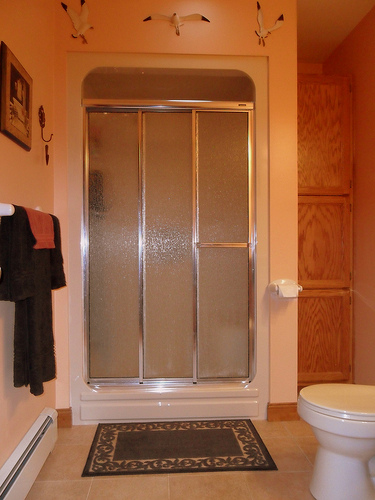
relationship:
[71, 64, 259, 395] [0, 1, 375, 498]
shower in corner of bathroom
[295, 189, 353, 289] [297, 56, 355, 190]
cabinet below cabinet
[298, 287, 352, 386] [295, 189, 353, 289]
wooden cabinet below cabinet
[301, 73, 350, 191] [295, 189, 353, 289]
cabinet above cabinet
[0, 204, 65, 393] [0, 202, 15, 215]
black towel hanging on rack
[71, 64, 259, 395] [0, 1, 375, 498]
shower in bathroom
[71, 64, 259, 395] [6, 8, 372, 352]
shower in bathroom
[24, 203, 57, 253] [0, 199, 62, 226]
towel on rack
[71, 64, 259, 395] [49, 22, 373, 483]
shower in corner of bathroom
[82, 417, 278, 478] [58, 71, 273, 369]
bath mat in front of shower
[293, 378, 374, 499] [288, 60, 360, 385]
toilet next to cabinet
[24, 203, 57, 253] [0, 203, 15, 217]
towel hanging on rack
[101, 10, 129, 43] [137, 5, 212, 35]
wall has decoration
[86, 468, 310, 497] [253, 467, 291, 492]
tile on floor